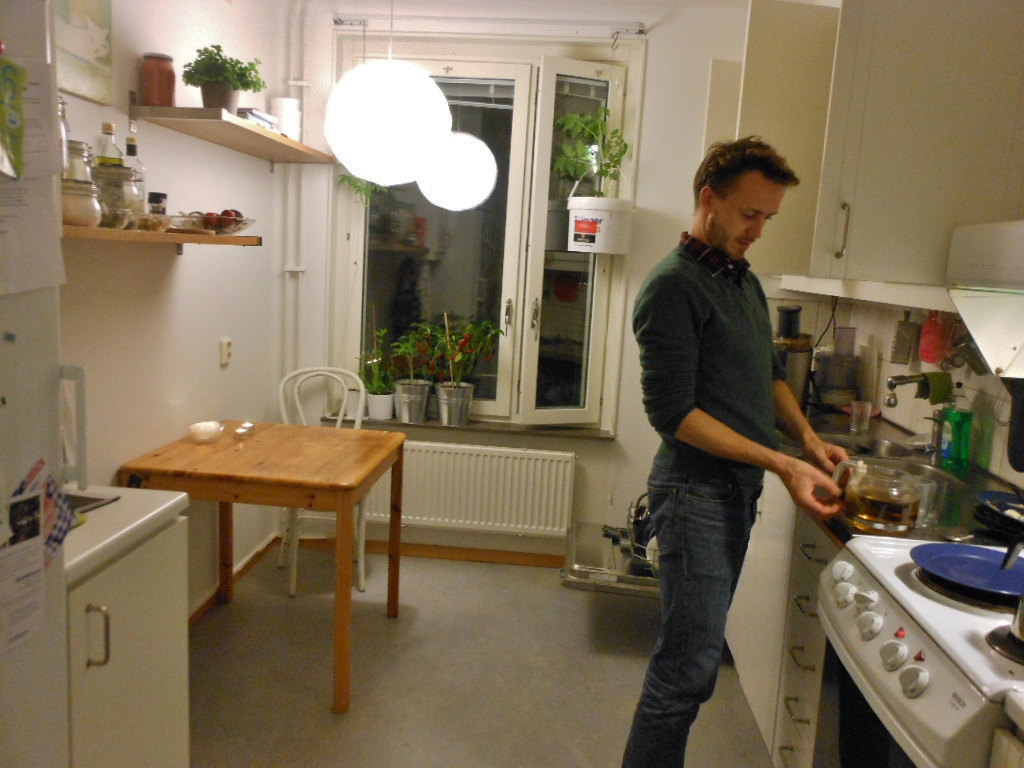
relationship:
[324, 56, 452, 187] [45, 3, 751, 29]
light hanging from ceiling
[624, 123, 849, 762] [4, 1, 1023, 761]
man standing in kitchen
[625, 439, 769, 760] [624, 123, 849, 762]
jeans worn by man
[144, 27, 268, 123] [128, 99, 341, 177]
plant on shelf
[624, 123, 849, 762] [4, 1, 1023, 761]
man in kitchen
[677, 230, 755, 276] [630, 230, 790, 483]
collar on shirt